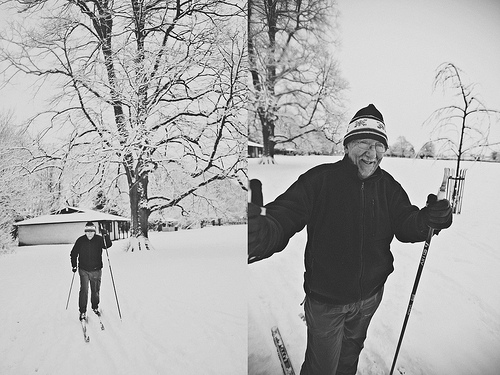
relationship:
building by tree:
[13, 203, 116, 246] [4, 1, 244, 248]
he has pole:
[247, 103, 454, 374] [386, 162, 453, 374]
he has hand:
[247, 103, 454, 374] [418, 191, 483, 239]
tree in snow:
[423, 59, 495, 217] [247, 154, 497, 374]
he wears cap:
[247, 103, 454, 374] [344, 104, 386, 147]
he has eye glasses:
[247, 103, 454, 374] [346, 136, 390, 151]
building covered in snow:
[13, 206, 131, 247] [121, 254, 211, 361]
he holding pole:
[247, 103, 454, 374] [387, 177, 455, 375]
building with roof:
[13, 206, 131, 247] [13, 207, 122, 230]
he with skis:
[70, 221, 114, 325] [70, 252, 75, 317]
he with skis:
[70, 221, 114, 325] [100, 237, 127, 312]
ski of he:
[268, 316, 298, 374] [247, 103, 454, 374]